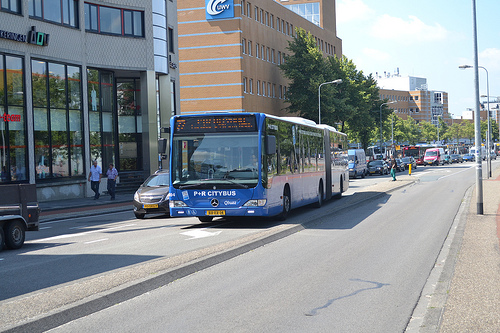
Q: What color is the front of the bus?
A: Blue.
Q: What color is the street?
A: Gray.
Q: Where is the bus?
A: Street.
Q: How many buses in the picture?
A: One.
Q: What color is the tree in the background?
A: Green.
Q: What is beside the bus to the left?
A: Car.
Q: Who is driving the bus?
A: Driver.